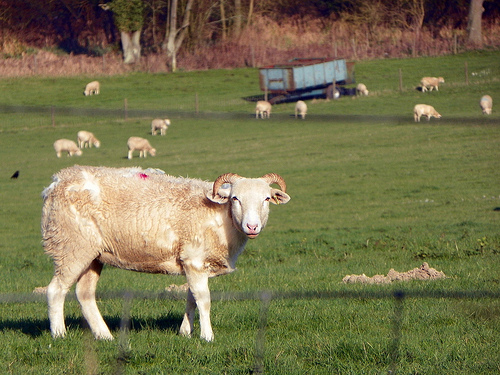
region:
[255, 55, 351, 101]
A blue trailer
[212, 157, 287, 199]
The horns of a ram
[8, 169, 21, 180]
A black bird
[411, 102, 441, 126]
A sheep grazing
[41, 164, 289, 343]
A ram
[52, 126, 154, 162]
Three sheep grazing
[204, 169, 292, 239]
The head of a ram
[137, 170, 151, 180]
A purple marking on the back of a ram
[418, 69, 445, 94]
A sheep walking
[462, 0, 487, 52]
The trunk of a tree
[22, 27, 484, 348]
sheep standing on green meadow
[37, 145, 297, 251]
red dot on sheep's back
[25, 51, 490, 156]
sheep scattered across a meadow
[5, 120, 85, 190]
blackbird facing sheep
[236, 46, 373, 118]
tilted rectangular and blue truck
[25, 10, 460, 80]
tan plants along meadow border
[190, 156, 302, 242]
horns curled above ears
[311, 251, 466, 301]
wide pile of tan matter on grass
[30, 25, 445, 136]
poles supporting fencing dividing meadow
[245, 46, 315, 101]
rusted edges on back of truck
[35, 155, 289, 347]
The sheep with the red dot on its back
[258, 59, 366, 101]
The blue bed of a truck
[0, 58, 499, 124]
The fence half way through the field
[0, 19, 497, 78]
The brown grass in the bakcground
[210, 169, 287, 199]
The horns on the sheep nearest the camera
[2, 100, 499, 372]
The fence between the camera and the sheep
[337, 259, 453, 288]
Dirt pile in the field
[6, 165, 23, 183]
Black object on the grass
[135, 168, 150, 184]
Red dot on the sheep's back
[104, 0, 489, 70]
The trees in the background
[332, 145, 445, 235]
part of a green field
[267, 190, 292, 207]
left ear of a goat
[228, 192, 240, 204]
right eye of a goat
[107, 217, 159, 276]
stomach of a goat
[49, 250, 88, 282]
right hind thigh of a goat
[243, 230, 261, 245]
mouth of a goat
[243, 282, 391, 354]
part of a net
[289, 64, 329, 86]
part of a blue container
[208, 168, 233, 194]
right horn of the goat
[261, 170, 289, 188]
left horn of the goat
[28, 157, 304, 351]
adult ram with dirty white fur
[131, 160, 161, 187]
red spot on white wool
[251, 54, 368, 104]
powder blue trailer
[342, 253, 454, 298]
dung pile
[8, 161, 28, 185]
black bird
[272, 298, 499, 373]
lush green grass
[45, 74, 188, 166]
5 grazing sheep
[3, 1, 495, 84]
edge of the woods touching the field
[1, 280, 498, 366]
close out of focus fence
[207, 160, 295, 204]
yellow downturned ram horns